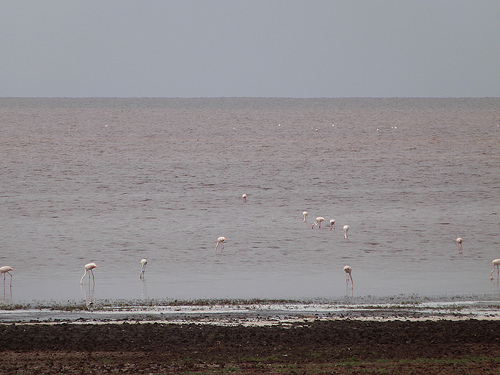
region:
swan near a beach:
[73, 241, 115, 301]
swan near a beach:
[132, 251, 166, 292]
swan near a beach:
[333, 249, 370, 317]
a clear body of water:
[69, 131, 176, 203]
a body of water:
[29, 118, 151, 229]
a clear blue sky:
[136, 19, 254, 80]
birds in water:
[4, 135, 452, 313]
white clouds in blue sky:
[295, 36, 337, 74]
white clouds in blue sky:
[184, 35, 218, 73]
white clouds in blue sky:
[45, 29, 90, 60]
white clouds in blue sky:
[187, 16, 248, 57]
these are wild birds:
[56, 191, 401, 306]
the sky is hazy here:
[51, 20, 231, 85]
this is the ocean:
[72, 104, 294, 216]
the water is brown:
[72, 130, 212, 222]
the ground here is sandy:
[124, 305, 217, 362]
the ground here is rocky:
[286, 315, 376, 362]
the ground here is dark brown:
[198, 336, 284, 361]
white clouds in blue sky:
[49, 21, 73, 42]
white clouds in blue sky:
[374, 0, 398, 25]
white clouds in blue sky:
[330, 51, 379, 77]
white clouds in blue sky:
[210, 15, 237, 42]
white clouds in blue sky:
[273, 36, 304, 66]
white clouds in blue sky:
[134, 37, 169, 62]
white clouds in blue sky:
[97, 28, 144, 60]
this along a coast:
[30, 23, 475, 348]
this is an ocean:
[76, 112, 319, 266]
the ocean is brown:
[78, 131, 183, 223]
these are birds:
[46, 224, 455, 315]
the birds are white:
[70, 249, 181, 284]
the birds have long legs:
[66, 247, 113, 296]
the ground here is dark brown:
[105, 315, 238, 368]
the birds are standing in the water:
[296, 197, 381, 293]